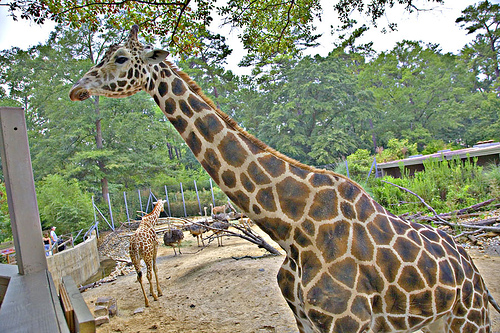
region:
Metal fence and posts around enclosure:
[76, 146, 391, 237]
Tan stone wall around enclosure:
[10, 203, 111, 288]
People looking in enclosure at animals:
[18, 220, 77, 255]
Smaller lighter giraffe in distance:
[115, 183, 185, 315]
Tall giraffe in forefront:
[58, 16, 498, 328]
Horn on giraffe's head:
[114, 23, 149, 42]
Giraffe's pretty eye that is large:
[111, 48, 136, 68]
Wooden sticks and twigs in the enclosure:
[164, 173, 497, 260]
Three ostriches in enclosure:
[152, 202, 238, 252]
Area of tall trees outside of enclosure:
[2, 0, 497, 271]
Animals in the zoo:
[64, 26, 495, 318]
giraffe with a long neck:
[56, 34, 353, 236]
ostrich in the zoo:
[163, 203, 228, 252]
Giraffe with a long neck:
[140, 68, 332, 248]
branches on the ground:
[404, 177, 492, 249]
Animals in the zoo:
[50, 34, 481, 329]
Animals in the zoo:
[65, 31, 382, 325]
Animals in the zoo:
[66, 5, 401, 329]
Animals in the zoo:
[57, 28, 457, 331]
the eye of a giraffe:
[113, 51, 129, 64]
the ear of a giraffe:
[142, 48, 171, 62]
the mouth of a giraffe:
[68, 77, 99, 106]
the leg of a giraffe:
[134, 276, 151, 306]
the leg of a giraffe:
[145, 273, 162, 300]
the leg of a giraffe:
[149, 273, 166, 297]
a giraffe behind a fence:
[67, 22, 499, 332]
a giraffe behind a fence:
[128, 198, 167, 308]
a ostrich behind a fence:
[158, 215, 188, 258]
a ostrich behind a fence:
[181, 205, 212, 249]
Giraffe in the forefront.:
[70, 19, 495, 329]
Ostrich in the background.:
[160, 213, 187, 259]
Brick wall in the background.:
[45, 225, 104, 290]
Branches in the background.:
[380, 180, 495, 248]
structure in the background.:
[372, 140, 499, 186]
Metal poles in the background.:
[87, 179, 219, 232]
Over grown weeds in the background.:
[363, 146, 480, 224]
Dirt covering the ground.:
[85, 216, 297, 331]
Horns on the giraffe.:
[117, 11, 141, 53]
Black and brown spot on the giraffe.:
[317, 217, 349, 262]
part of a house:
[373, 159, 406, 191]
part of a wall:
[99, 200, 107, 221]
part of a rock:
[338, 255, 356, 274]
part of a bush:
[382, 196, 404, 216]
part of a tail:
[92, 238, 143, 281]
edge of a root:
[230, 238, 244, 273]